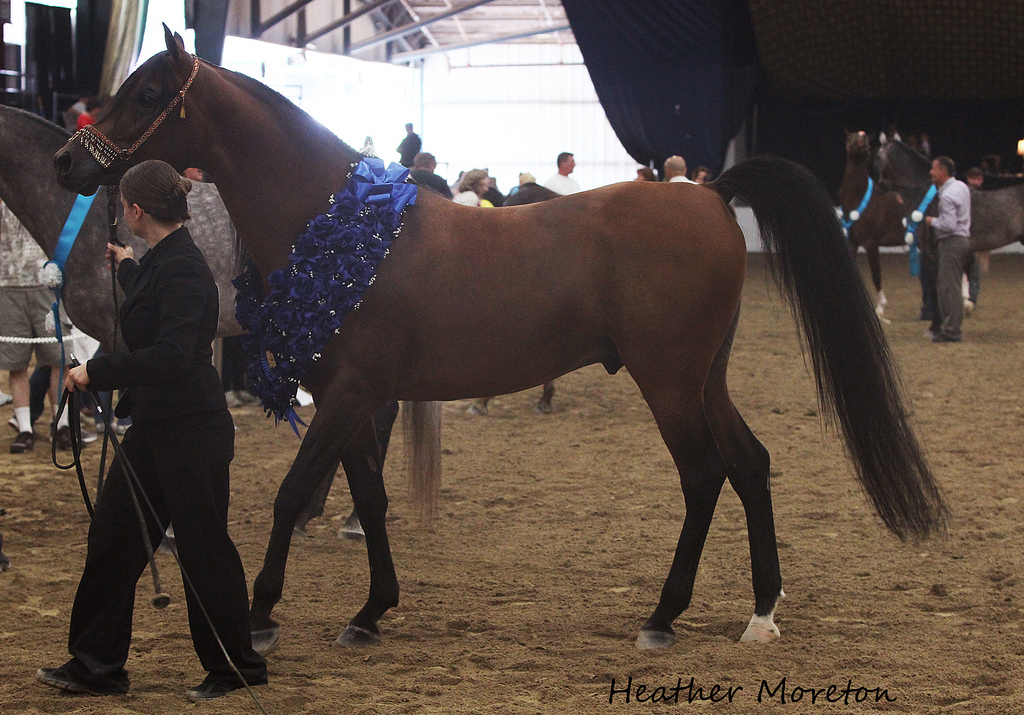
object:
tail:
[719, 156, 943, 538]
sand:
[5, 253, 1024, 683]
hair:
[120, 160, 192, 221]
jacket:
[86, 227, 228, 424]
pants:
[70, 409, 266, 670]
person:
[38, 162, 285, 703]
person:
[663, 156, 700, 185]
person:
[412, 153, 452, 198]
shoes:
[38, 668, 127, 697]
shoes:
[11, 431, 34, 453]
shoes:
[934, 332, 960, 341]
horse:
[840, 132, 903, 304]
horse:
[0, 101, 233, 342]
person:
[452, 169, 489, 206]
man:
[925, 156, 972, 341]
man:
[544, 152, 579, 195]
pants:
[939, 236, 963, 336]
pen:
[8, 143, 1021, 695]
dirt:
[469, 444, 616, 595]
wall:
[221, 35, 424, 158]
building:
[0, 0, 1023, 250]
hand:
[925, 216, 932, 224]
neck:
[205, 64, 333, 262]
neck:
[146, 220, 182, 250]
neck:
[841, 159, 868, 222]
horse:
[53, 22, 952, 651]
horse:
[877, 133, 1024, 318]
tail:
[409, 401, 442, 525]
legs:
[610, 254, 741, 649]